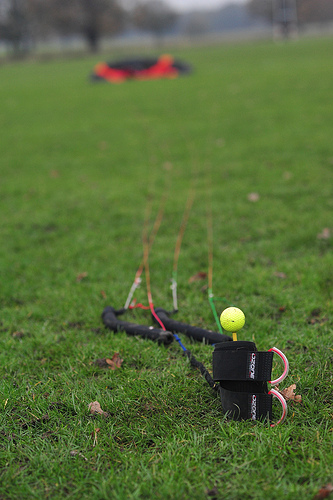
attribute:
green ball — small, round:
[218, 305, 248, 331]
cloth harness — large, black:
[209, 337, 276, 423]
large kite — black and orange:
[81, 50, 193, 83]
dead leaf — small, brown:
[104, 348, 122, 372]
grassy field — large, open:
[2, 47, 319, 498]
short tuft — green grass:
[144, 405, 190, 435]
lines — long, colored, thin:
[104, 113, 234, 332]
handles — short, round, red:
[263, 344, 301, 389]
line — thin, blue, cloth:
[170, 333, 184, 357]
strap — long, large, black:
[86, 309, 182, 346]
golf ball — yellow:
[215, 305, 245, 329]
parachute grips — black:
[204, 348, 274, 423]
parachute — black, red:
[86, 50, 198, 100]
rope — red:
[117, 99, 176, 323]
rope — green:
[198, 288, 250, 340]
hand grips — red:
[262, 339, 290, 440]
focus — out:
[5, 6, 322, 164]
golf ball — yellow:
[222, 306, 247, 339]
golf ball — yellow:
[218, 308, 251, 329]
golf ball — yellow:
[215, 298, 247, 337]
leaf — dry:
[276, 379, 310, 405]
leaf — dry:
[280, 382, 304, 406]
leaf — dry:
[276, 375, 302, 408]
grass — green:
[12, 49, 314, 489]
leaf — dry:
[272, 381, 309, 405]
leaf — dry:
[276, 379, 302, 405]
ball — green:
[219, 301, 245, 331]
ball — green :
[220, 306, 244, 332]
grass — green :
[2, 39, 328, 493]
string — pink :
[134, 303, 164, 330]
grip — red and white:
[268, 344, 292, 429]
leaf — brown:
[185, 264, 217, 287]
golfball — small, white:
[217, 305, 246, 329]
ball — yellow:
[218, 302, 248, 331]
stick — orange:
[227, 332, 239, 340]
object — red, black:
[126, 293, 168, 334]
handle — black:
[97, 299, 166, 344]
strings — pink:
[134, 222, 238, 325]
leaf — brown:
[85, 398, 108, 419]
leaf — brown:
[279, 378, 302, 402]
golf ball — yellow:
[212, 298, 256, 341]